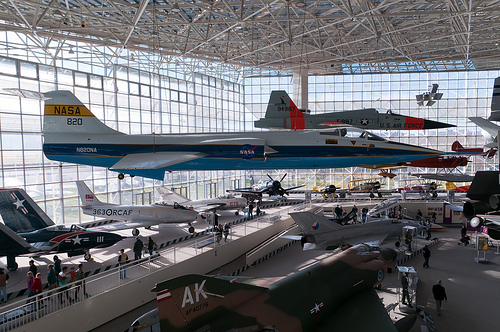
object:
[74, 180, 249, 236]
two planes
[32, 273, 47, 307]
person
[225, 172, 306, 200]
sign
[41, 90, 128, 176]
tail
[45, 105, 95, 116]
nasa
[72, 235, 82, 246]
stars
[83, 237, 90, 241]
stripes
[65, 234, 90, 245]
logo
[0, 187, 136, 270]
jet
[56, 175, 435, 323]
plane museum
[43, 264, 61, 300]
people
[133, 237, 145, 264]
people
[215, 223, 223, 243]
people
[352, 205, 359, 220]
people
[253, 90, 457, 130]
plane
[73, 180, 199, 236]
stuffed animals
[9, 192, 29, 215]
logo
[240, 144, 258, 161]
nasa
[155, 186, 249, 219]
plane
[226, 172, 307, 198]
plane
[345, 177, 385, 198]
plane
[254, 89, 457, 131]
airplane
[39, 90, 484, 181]
airplane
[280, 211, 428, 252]
airplane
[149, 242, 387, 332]
airplane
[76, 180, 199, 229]
airplane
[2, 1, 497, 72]
ceiling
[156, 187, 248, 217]
small plane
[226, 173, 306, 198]
small plane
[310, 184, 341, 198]
small plane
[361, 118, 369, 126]
us logo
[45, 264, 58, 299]
visitors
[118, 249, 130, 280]
person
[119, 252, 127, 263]
yellow shirt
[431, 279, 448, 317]
person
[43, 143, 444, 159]
stripe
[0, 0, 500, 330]
showroom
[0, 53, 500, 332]
hangar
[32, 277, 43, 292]
shirt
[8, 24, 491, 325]
museum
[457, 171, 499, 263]
plane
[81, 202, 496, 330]
floor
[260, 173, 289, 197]
propeller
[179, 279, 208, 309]
ak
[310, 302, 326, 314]
logo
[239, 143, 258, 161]
stars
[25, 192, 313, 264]
walkway